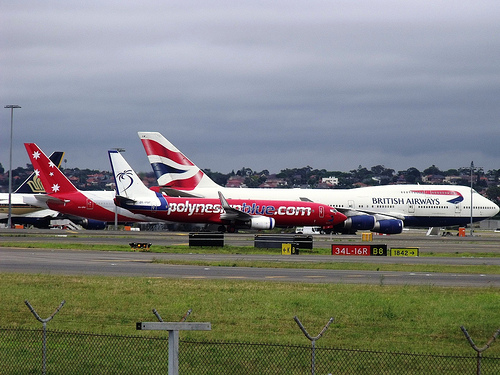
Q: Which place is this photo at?
A: It is at the airport.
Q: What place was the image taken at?
A: It was taken at the airport.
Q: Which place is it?
A: It is an airport.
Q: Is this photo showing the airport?
A: Yes, it is showing the airport.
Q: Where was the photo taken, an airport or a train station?
A: It was taken at an airport.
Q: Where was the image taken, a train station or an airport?
A: It was taken at an airport.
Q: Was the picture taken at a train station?
A: No, the picture was taken in an airport.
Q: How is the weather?
A: It is cloudy.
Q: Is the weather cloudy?
A: Yes, it is cloudy.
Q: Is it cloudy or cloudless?
A: It is cloudy.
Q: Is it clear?
A: No, it is cloudy.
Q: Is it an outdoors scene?
A: Yes, it is outdoors.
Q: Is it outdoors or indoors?
A: It is outdoors.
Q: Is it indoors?
A: No, it is outdoors.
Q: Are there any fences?
A: Yes, there is a fence.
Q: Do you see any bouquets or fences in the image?
A: Yes, there is a fence.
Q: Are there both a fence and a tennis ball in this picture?
A: No, there is a fence but no tennis balls.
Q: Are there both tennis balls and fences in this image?
A: No, there is a fence but no tennis balls.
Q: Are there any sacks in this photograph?
A: No, there are no sacks.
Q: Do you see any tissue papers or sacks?
A: No, there are no sacks or tissue papers.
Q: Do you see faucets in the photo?
A: No, there are no faucets.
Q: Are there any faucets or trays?
A: No, there are no faucets or trays.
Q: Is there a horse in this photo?
A: No, there are no horses.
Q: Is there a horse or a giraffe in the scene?
A: No, there are no horses or giraffes.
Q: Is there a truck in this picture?
A: No, there are no trucks.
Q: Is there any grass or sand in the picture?
A: Yes, there is grass.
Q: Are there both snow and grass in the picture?
A: No, there is grass but no snow.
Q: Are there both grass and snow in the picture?
A: No, there is grass but no snow.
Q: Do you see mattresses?
A: No, there are no mattresses.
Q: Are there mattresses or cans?
A: No, there are no mattresses or cans.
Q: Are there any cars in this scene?
A: No, there are no cars.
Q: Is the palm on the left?
A: Yes, the palm is on the left of the image.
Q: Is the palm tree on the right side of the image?
A: No, the palm tree is on the left of the image.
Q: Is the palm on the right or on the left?
A: The palm is on the left of the image.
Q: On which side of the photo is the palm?
A: The palm is on the left of the image.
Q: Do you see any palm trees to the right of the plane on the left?
A: Yes, there is a palm tree to the right of the plane.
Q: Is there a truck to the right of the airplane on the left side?
A: No, there is a palm tree to the right of the airplane.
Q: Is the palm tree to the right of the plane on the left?
A: Yes, the palm tree is to the right of the plane.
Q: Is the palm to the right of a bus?
A: No, the palm is to the right of the plane.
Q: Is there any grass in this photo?
A: Yes, there is grass.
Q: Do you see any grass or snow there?
A: Yes, there is grass.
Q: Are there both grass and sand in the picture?
A: No, there is grass but no sand.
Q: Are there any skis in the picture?
A: No, there are no skis.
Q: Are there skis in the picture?
A: No, there are no skis.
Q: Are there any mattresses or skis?
A: No, there are no skis or mattresses.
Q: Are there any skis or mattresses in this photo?
A: No, there are no skis or mattresses.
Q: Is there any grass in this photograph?
A: Yes, there is grass.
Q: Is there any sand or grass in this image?
A: Yes, there is grass.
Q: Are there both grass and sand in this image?
A: No, there is grass but no sand.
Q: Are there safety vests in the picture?
A: No, there are no safety vests.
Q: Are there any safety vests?
A: No, there are no safety vests.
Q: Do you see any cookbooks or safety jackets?
A: No, there are no safety jackets or cookbooks.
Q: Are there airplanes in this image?
A: Yes, there is an airplane.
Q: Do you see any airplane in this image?
A: Yes, there is an airplane.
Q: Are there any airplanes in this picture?
A: Yes, there is an airplane.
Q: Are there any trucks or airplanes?
A: Yes, there is an airplane.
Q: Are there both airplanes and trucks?
A: No, there is an airplane but no trucks.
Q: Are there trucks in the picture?
A: No, there are no trucks.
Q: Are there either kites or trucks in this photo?
A: No, there are no trucks or kites.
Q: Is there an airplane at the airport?
A: Yes, there is an airplane at the airport.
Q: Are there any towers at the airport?
A: No, there is an airplane at the airport.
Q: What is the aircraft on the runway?
A: The aircraft is an airplane.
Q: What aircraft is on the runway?
A: The aircraft is an airplane.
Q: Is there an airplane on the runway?
A: Yes, there is an airplane on the runway.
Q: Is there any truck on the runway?
A: No, there is an airplane on the runway.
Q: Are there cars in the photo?
A: No, there are no cars.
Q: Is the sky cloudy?
A: Yes, the sky is cloudy.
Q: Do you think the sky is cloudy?
A: Yes, the sky is cloudy.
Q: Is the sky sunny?
A: No, the sky is cloudy.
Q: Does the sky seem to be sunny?
A: No, the sky is cloudy.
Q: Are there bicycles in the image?
A: No, there are no bicycles.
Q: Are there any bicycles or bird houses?
A: No, there are no bicycles or bird houses.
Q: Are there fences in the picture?
A: Yes, there is a fence.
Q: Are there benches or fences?
A: Yes, there is a fence.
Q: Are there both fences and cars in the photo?
A: No, there is a fence but no cars.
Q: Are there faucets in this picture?
A: No, there are no faucets.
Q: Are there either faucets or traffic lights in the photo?
A: No, there are no faucets or traffic lights.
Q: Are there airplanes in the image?
A: Yes, there is an airplane.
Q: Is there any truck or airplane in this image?
A: Yes, there is an airplane.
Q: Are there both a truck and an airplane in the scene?
A: No, there is an airplane but no trucks.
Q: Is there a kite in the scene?
A: No, there are no kites.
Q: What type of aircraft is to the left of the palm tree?
A: The aircraft is an airplane.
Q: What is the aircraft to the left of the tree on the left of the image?
A: The aircraft is an airplane.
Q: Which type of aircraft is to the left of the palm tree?
A: The aircraft is an airplane.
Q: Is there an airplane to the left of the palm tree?
A: Yes, there is an airplane to the left of the palm tree.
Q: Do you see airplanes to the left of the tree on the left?
A: Yes, there is an airplane to the left of the palm tree.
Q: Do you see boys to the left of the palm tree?
A: No, there is an airplane to the left of the palm tree.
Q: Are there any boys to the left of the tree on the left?
A: No, there is an airplane to the left of the palm tree.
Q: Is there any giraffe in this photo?
A: No, there are no giraffes.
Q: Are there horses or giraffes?
A: No, there are no giraffes or horses.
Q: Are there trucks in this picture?
A: No, there are no trucks.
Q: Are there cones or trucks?
A: No, there are no trucks or cones.